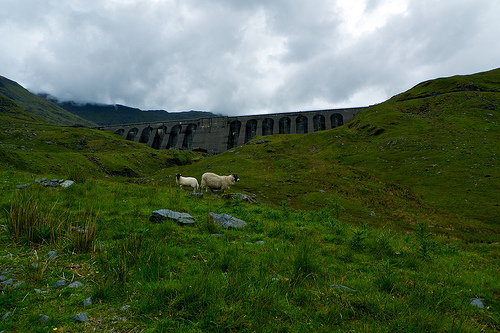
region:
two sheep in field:
[162, 169, 252, 187]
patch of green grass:
[74, 231, 187, 310]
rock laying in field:
[146, 195, 189, 238]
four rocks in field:
[44, 268, 93, 326]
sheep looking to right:
[200, 165, 251, 201]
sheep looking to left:
[167, 169, 200, 192]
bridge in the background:
[153, 97, 329, 154]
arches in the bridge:
[275, 114, 307, 134]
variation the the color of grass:
[358, 180, 414, 216]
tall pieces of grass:
[61, 195, 96, 257]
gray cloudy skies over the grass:
[0, 0, 499, 119]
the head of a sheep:
[174, 169, 182, 181]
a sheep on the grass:
[172, 170, 200, 193]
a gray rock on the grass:
[143, 204, 197, 230]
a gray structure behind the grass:
[78, 104, 372, 156]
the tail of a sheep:
[195, 177, 202, 190]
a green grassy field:
[1, 67, 499, 331]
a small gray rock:
[68, 309, 90, 325]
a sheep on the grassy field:
[197, 166, 242, 196]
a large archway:
[163, 121, 182, 154]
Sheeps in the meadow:
[168, 161, 246, 195]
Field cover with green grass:
[16, 125, 465, 328]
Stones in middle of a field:
[145, 201, 249, 243]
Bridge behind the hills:
[106, 102, 358, 151]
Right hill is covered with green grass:
[246, 56, 497, 223]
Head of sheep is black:
[168, 166, 200, 200]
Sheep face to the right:
[196, 166, 247, 201]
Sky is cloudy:
[7, 5, 497, 80]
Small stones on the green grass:
[5, 249, 120, 331]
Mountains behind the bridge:
[40, 84, 211, 121]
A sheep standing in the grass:
[201, 164, 256, 196]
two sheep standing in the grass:
[167, 167, 244, 195]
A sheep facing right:
[201, 164, 242, 197]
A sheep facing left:
[170, 164, 197, 191]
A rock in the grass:
[212, 203, 257, 245]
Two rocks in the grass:
[143, 199, 278, 250]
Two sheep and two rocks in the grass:
[157, 160, 251, 260]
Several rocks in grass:
[20, 226, 129, 325]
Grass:
[199, 236, 378, 294]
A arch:
[228, 104, 249, 162]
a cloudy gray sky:
[0, 0, 496, 117]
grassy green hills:
[0, 65, 496, 330]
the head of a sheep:
[225, 170, 240, 181]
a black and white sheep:
[198, 171, 243, 199]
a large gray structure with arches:
[91, 100, 373, 156]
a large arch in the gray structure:
[223, 115, 243, 155]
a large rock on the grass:
[205, 207, 247, 233]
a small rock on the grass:
[72, 309, 92, 324]